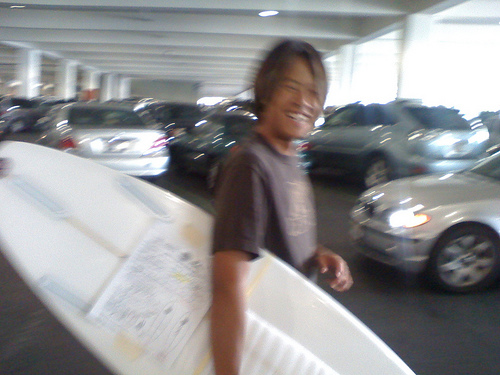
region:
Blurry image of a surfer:
[197, 37, 357, 322]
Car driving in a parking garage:
[329, 149, 499, 281]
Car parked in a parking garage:
[18, 102, 175, 179]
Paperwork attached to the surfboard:
[89, 239, 227, 359]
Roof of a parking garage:
[54, 13, 196, 67]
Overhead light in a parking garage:
[246, 5, 283, 22]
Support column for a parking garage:
[55, 55, 79, 113]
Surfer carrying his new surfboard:
[23, 30, 423, 374]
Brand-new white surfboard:
[6, 139, 431, 374]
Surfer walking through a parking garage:
[190, 36, 361, 374]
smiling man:
[240, 25, 311, 109]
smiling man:
[244, 12, 348, 172]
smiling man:
[210, 24, 321, 228]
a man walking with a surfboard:
[0, 39, 371, 370]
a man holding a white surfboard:
[12, 31, 493, 373]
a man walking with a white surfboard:
[32, 14, 490, 317]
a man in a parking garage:
[74, 10, 431, 372]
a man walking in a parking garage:
[39, 25, 381, 371]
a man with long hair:
[54, 40, 492, 310]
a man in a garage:
[54, 27, 382, 367]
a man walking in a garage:
[99, 18, 478, 360]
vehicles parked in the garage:
[312, 85, 498, 310]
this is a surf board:
[4, 137, 417, 372]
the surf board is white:
[0, 130, 407, 372]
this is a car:
[341, 162, 494, 297]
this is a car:
[303, 98, 493, 181]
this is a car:
[176, 111, 290, 169]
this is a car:
[37, 85, 175, 184]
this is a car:
[1, 98, 48, 133]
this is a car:
[142, 89, 200, 123]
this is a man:
[194, 43, 354, 373]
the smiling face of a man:
[246, 38, 332, 141]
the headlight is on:
[382, 203, 432, 238]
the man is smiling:
[184, 34, 372, 373]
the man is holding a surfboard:
[206, 24, 358, 367]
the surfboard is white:
[0, 126, 391, 365]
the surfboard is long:
[2, 141, 379, 368]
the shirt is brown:
[220, 117, 319, 262]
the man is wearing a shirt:
[210, 132, 342, 276]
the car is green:
[181, 117, 224, 170]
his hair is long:
[258, 56, 275, 100]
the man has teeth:
[284, 103, 316, 128]